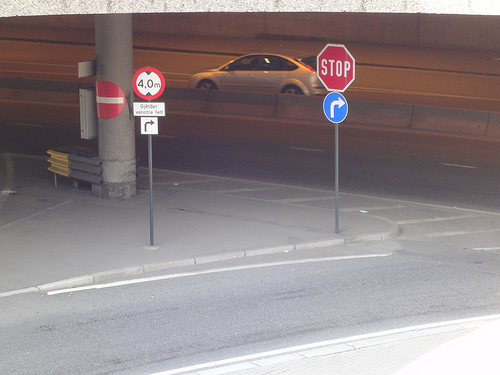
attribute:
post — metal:
[332, 127, 352, 230]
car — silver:
[205, 39, 352, 153]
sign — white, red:
[99, 71, 199, 106]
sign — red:
[310, 38, 343, 70]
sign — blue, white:
[313, 96, 345, 111]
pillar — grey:
[96, 44, 128, 76]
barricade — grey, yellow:
[33, 128, 115, 210]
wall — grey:
[219, 63, 291, 143]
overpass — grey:
[343, 73, 438, 142]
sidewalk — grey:
[319, 343, 439, 373]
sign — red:
[305, 41, 363, 111]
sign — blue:
[309, 77, 363, 126]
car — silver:
[183, 65, 307, 105]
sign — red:
[104, 65, 112, 112]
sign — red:
[139, 66, 177, 133]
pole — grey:
[82, 109, 188, 185]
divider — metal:
[25, 145, 137, 245]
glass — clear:
[243, 44, 283, 75]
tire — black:
[201, 73, 223, 97]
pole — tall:
[72, 51, 204, 217]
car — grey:
[176, 49, 401, 137]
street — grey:
[202, 267, 299, 346]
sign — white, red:
[319, 38, 361, 100]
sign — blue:
[306, 107, 362, 114]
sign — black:
[118, 96, 198, 160]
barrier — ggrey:
[7, 144, 118, 204]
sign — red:
[89, 62, 138, 147]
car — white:
[224, 60, 305, 128]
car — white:
[209, 0, 299, 108]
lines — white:
[164, 240, 245, 304]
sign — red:
[272, 35, 387, 104]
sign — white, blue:
[310, 57, 378, 122]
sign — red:
[316, 40, 368, 84]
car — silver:
[221, 54, 319, 124]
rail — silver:
[55, 150, 93, 162]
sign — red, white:
[121, 44, 201, 130]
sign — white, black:
[127, 70, 159, 165]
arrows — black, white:
[112, 93, 450, 153]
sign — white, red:
[61, 60, 190, 168]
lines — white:
[250, 240, 305, 294]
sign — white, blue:
[302, 65, 386, 135]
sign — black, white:
[96, 112, 251, 152]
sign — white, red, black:
[126, 39, 182, 114]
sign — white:
[134, 85, 183, 144]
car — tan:
[264, 25, 299, 141]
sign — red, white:
[50, 43, 160, 144]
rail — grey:
[30, 150, 95, 195]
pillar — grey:
[44, 43, 185, 187]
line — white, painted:
[439, 159, 476, 169]